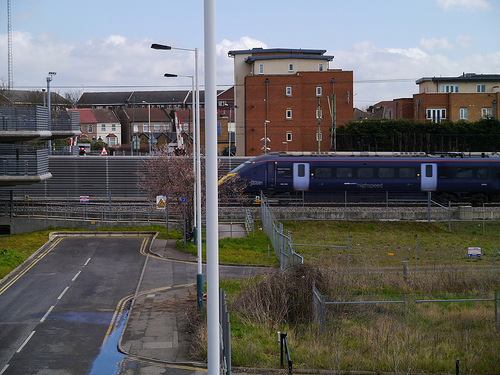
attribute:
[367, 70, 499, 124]
buildings — tan, brown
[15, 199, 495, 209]
tracks — train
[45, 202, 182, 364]
road — dead-end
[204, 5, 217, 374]
white pole — tall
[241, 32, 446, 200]
building — large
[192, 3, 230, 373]
pole — tall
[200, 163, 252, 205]
nose — yellow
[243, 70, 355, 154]
building — red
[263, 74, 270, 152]
pole — gray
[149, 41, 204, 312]
street light — tall, overhead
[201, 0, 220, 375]
pole — metal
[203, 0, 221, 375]
pole — white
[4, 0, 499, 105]
blue sky — cloudy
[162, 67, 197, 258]
street light — tall, overhead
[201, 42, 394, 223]
building — tall, brown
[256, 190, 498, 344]
fence — chain link, silver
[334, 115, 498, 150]
trees row — tall, green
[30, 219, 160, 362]
pavement — black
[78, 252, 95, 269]
stripes — white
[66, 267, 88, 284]
stripes — white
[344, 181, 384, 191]
writing — yellow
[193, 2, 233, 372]
pole — white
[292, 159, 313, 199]
door — white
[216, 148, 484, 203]
train — yellow, blue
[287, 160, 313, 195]
door — white